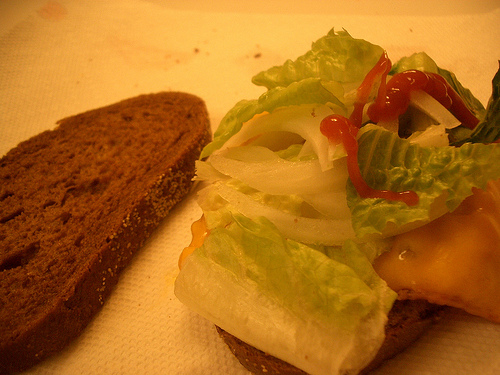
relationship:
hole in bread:
[4, 240, 43, 272] [2, 70, 214, 356]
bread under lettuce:
[230, 318, 418, 369] [183, 28, 483, 369]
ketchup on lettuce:
[334, 62, 481, 202] [183, 28, 483, 369]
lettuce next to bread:
[183, 28, 483, 369] [2, 70, 214, 356]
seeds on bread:
[147, 174, 191, 220] [2, 70, 214, 356]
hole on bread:
[4, 240, 43, 272] [2, 70, 214, 356]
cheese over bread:
[386, 194, 499, 313] [230, 318, 418, 369]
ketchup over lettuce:
[334, 62, 481, 202] [183, 28, 483, 369]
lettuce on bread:
[183, 28, 483, 369] [2, 70, 214, 356]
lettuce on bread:
[183, 28, 483, 369] [230, 318, 418, 369]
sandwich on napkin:
[4, 26, 500, 371] [336, 4, 497, 67]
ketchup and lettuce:
[334, 62, 481, 202] [183, 28, 483, 369]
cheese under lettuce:
[386, 194, 499, 313] [183, 28, 483, 369]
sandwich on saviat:
[4, 26, 500, 371] [5, 7, 275, 117]